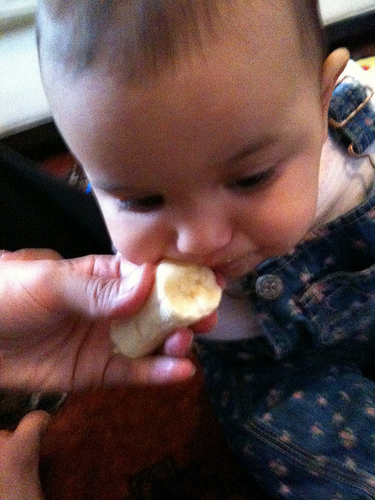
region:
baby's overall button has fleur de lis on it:
[255, 272, 282, 300]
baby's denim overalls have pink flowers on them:
[277, 428, 294, 446]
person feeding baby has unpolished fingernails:
[23, 252, 223, 437]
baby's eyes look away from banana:
[97, 153, 285, 218]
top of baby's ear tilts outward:
[320, 41, 352, 155]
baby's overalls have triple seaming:
[240, 412, 372, 498]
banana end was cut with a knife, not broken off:
[104, 316, 139, 364]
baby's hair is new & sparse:
[24, 0, 335, 112]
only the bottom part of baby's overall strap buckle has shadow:
[338, 135, 374, 204]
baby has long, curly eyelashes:
[108, 188, 142, 218]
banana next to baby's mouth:
[105, 259, 230, 358]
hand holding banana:
[6, 246, 220, 392]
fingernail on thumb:
[118, 263, 153, 295]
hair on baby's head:
[31, 0, 327, 91]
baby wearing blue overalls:
[193, 102, 370, 496]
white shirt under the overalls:
[319, 133, 374, 212]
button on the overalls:
[257, 274, 283, 299]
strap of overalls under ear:
[327, 73, 373, 184]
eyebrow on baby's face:
[209, 127, 297, 166]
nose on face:
[175, 212, 231, 256]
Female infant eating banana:
[17, 1, 338, 378]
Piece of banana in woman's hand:
[4, 256, 230, 388]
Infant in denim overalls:
[28, 0, 373, 498]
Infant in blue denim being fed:
[26, 0, 373, 493]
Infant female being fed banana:
[35, 75, 371, 392]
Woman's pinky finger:
[93, 350, 200, 388]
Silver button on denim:
[251, 271, 293, 306]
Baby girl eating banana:
[28, 40, 320, 371]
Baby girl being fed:
[33, 56, 340, 362]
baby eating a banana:
[2, 2, 374, 498]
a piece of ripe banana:
[110, 257, 222, 357]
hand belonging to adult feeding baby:
[3, 252, 229, 396]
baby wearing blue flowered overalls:
[186, 100, 374, 499]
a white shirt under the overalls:
[129, 134, 373, 340]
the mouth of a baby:
[142, 248, 270, 283]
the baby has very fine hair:
[25, 0, 328, 78]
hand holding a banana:
[0, 251, 226, 384]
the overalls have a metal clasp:
[218, 270, 288, 303]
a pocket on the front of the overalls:
[295, 248, 373, 349]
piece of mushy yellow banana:
[108, 260, 219, 352]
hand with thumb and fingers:
[0, 247, 212, 387]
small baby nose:
[178, 222, 231, 254]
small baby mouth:
[164, 254, 265, 271]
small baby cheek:
[238, 184, 324, 249]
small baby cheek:
[110, 213, 166, 258]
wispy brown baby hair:
[35, 1, 336, 87]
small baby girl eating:
[32, 1, 372, 488]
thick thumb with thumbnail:
[4, 409, 50, 496]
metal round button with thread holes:
[256, 274, 282, 295]